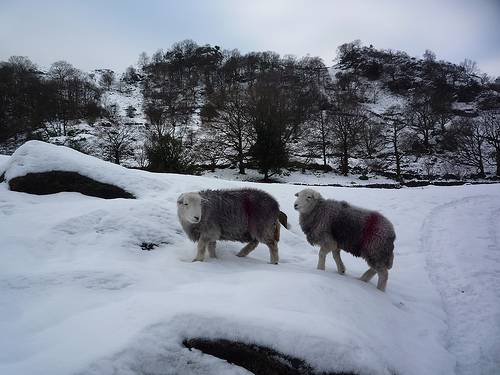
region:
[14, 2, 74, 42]
white clouds in blue sky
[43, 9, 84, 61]
white clouds in blue sky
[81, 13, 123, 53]
white clouds in blue sky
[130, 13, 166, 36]
white clouds in blue sky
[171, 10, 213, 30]
white clouds in blue sky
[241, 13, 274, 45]
white clouds in blue sky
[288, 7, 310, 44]
white clouds in blue sky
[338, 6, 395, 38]
white clouds in blue sky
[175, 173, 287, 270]
white and brown sheep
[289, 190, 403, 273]
white and brown sheep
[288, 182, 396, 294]
the sheep climbs the snowy bank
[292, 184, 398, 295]
the sheep has a red paint marker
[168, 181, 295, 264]
the lead sheep looks over its shoulder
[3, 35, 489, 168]
trees at the top of the hill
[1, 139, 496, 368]
snow covers the hillside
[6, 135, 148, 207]
a rock juts from the snow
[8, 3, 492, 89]
the sky is cold and cloudy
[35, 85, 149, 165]
snow visible between the trees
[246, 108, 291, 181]
an evergreen tree among the others trees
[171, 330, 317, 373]
part of the hill exposed from the snow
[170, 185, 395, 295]
gray sheep on white snow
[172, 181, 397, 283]
one sheep following the other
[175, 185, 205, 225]
white head over body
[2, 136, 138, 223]
snow on top of angled rock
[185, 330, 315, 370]
dark wedge between snow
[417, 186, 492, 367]
used path with curve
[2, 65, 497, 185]
trees on snow covered slope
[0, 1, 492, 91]
faint clouds over blue sky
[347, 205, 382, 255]
dark orange stripe over body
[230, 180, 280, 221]
darker wool on back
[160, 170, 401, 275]
Two sheep in the snow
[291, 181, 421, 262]
A sheep with a red stripe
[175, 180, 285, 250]
A sheep with a red stripe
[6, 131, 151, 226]
Snow covered rock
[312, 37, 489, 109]
Trees on a mountain top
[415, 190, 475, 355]
Tracks in the snow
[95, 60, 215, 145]
Snow covered mountain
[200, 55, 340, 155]
A large tree behind sheep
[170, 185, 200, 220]
Sheep with a white face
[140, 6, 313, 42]
Blue skies behind trees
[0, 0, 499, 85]
a large patch of sky in the background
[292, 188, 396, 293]
a sheep with a red spot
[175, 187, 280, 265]
a sheep on the left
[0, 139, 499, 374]
a snowy, hilly landscape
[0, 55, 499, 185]
a rocky hilly landscape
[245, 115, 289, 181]
a large pine tree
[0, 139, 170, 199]
a large rock outcropping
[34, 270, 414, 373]
a large rock in the foreground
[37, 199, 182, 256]
a smaller rock outcropping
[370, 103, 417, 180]
a large leafless tree